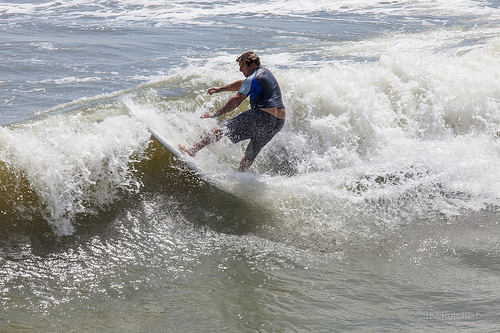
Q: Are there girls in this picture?
A: No, there are no girls.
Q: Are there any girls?
A: No, there are no girls.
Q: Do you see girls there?
A: No, there are no girls.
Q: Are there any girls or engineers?
A: No, there are no girls or engineers.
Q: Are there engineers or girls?
A: No, there are no girls or engineers.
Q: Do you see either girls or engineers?
A: No, there are no girls or engineers.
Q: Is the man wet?
A: Yes, the man is wet.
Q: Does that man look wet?
A: Yes, the man is wet.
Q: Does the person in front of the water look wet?
A: Yes, the man is wet.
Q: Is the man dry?
A: No, the man is wet.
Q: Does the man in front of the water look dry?
A: No, the man is wet.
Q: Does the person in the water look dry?
A: No, the man is wet.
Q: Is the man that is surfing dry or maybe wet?
A: The man is wet.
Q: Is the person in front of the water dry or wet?
A: The man is wet.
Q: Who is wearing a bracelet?
A: The man is wearing a bracelet.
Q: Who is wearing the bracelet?
A: The man is wearing a bracelet.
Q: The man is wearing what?
A: The man is wearing a bracelet.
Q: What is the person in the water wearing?
A: The man is wearing a bracelet.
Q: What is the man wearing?
A: The man is wearing a bracelet.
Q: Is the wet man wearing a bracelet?
A: Yes, the man is wearing a bracelet.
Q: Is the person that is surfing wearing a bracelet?
A: Yes, the man is wearing a bracelet.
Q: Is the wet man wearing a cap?
A: No, the man is wearing a bracelet.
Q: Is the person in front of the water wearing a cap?
A: No, the man is wearing a bracelet.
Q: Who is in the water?
A: The man is in the water.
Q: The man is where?
A: The man is in the water.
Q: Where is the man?
A: The man is in the water.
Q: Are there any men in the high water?
A: Yes, there is a man in the water.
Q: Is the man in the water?
A: Yes, the man is in the water.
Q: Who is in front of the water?
A: The man is in front of the water.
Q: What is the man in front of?
A: The man is in front of the water.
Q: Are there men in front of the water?
A: Yes, there is a man in front of the water.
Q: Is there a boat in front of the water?
A: No, there is a man in front of the water.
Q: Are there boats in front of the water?
A: No, there is a man in front of the water.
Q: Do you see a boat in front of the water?
A: No, there is a man in front of the water.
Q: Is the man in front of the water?
A: Yes, the man is in front of the water.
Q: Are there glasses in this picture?
A: No, there are no glasses.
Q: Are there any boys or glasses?
A: No, there are no glasses or boys.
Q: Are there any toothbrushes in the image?
A: No, there are no toothbrushes.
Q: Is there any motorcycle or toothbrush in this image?
A: No, there are no toothbrushes or motorcycles.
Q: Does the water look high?
A: Yes, the water is high.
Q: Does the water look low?
A: No, the water is high.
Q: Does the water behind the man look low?
A: No, the water is high.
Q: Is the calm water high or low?
A: The water is high.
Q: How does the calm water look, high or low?
A: The water is high.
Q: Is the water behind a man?
A: Yes, the water is behind a man.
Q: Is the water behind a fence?
A: No, the water is behind a man.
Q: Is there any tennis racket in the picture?
A: No, there are no rackets.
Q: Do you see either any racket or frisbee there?
A: No, there are no rackets or frisbees.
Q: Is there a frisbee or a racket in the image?
A: No, there are no rackets or frisbees.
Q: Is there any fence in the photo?
A: No, there are no fences.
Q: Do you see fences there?
A: No, there are no fences.